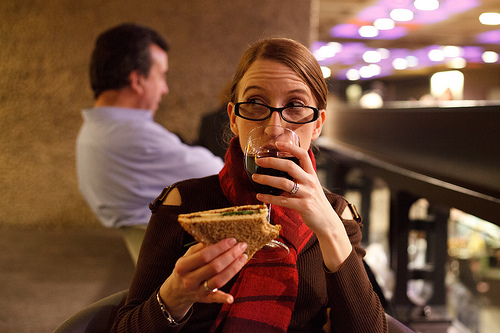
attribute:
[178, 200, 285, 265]
sandwich — held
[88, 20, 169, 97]
hair — short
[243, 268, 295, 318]
scarf — red, black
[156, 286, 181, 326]
bracelet — metal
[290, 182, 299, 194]
ring — silver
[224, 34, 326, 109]
hair — brown